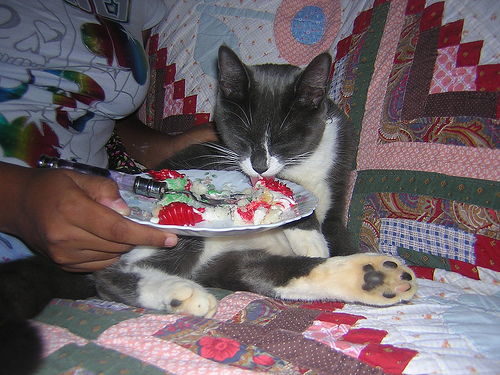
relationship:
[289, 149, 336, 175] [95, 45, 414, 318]
whisker of cat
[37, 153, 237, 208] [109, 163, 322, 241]
fork on plate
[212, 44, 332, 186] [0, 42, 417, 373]
head of a cat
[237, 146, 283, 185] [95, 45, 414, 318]
nose of cat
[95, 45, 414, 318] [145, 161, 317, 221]
cat eating cake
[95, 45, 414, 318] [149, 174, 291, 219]
cat eats cake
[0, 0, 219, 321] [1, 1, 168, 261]
woman has shirt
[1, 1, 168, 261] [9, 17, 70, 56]
shirt has hearts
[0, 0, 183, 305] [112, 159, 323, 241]
woman holding on white plate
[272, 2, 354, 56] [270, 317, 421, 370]
circular shapes on bedspread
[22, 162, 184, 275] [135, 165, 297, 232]
hand holds food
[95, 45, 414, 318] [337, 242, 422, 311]
cat has paw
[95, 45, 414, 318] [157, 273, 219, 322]
cat has paw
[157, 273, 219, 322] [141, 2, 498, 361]
paw on quilt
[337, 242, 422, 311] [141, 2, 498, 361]
paw on quilt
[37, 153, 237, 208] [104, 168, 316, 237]
fork on plate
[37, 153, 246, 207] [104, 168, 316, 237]
fork on plate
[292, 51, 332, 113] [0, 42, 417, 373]
ear of cat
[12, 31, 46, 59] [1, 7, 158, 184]
heart on woman's shirt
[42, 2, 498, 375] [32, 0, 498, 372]
quilt on couch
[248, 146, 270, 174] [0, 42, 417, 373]
nose of a cat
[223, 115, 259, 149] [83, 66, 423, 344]
eye of cat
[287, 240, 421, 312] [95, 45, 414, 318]
leg of cat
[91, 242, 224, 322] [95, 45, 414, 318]
leg of cat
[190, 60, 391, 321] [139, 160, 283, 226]
cat licking food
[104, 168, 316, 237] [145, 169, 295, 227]
plate with cake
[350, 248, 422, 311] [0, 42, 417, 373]
paw of cat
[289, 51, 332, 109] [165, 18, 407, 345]
ear of cat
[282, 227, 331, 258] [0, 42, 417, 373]
mitten on cat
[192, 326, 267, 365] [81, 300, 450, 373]
rose shapes on bedspread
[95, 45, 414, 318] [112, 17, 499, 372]
cat on couch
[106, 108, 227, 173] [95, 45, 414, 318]
hand on cat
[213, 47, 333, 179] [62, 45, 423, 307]
face of cat